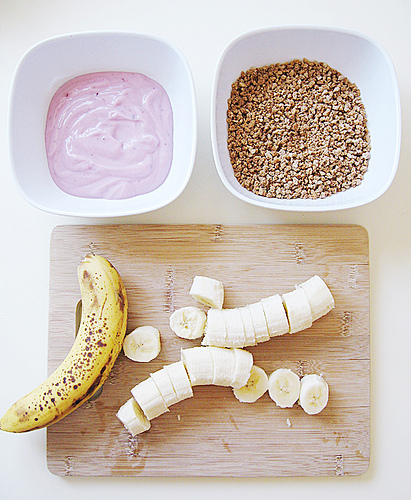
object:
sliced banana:
[233, 365, 269, 404]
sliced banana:
[230, 348, 254, 390]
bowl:
[211, 25, 402, 213]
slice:
[282, 275, 335, 335]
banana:
[115, 275, 335, 438]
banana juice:
[101, 430, 151, 476]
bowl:
[8, 31, 197, 219]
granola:
[227, 58, 371, 199]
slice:
[211, 346, 235, 385]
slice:
[116, 396, 152, 437]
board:
[45, 223, 371, 478]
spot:
[81, 314, 105, 366]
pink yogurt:
[44, 71, 173, 199]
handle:
[75, 299, 83, 338]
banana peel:
[86, 270, 104, 355]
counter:
[0, 0, 411, 497]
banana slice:
[268, 367, 328, 415]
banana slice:
[122, 326, 163, 364]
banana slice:
[169, 306, 205, 341]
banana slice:
[189, 275, 224, 310]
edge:
[48, 468, 376, 486]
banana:
[0, 252, 128, 434]